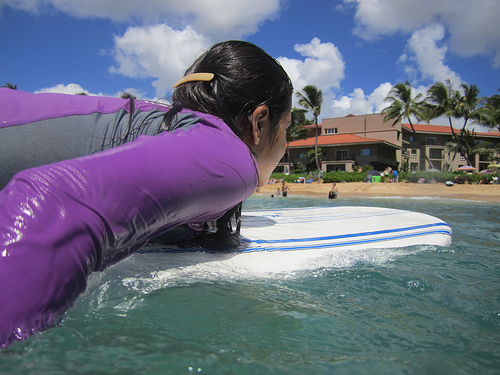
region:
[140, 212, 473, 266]
blue stripes on the surfboard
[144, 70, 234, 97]
hair barrett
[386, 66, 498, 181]
palm trees in front of building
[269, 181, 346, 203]
people in the water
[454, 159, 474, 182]
umbrella by the shrubs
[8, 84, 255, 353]
wetsuit is purple and grey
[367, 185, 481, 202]
water going on shoreline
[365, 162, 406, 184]
people on shore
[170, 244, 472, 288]
water on the surfboard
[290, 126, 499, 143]
roofs on the building are red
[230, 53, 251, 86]
hair of a lady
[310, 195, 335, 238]
part of a board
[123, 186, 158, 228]
part of a costume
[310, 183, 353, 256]
part of a board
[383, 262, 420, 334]
part of a water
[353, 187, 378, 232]
part of a board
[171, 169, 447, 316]
the surfboard is white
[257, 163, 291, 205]
people at the shore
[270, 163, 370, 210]
people at the shore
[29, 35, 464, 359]
a woman is in the water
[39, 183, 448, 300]
the woman is on a board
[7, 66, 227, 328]
the woman's wet suit is black and purple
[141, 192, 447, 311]
the woman's board is white with blue stripes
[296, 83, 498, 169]
palm trees are in the background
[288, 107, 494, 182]
a building sits on the beach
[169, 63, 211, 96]
the woman has a hair clip in her hair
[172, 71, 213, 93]
the hair clip is brown in color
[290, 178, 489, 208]
the ground is covered in sand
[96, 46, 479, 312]
the woman appears to be headed towards the beach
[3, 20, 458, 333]
woman lying on surfboard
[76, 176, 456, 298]
blue and white surfboard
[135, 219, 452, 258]
blue stripes on surfboard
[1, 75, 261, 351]
purple and black wetsuit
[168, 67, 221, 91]
wooden barrett in woman's dark hair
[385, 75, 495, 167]
tall green palm trees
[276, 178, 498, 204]
sand on border of body of water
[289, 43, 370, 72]
white cloud in dark blue sky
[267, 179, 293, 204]
person walking with child into shallow end of water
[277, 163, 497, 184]
green bushes in front of sand on beach